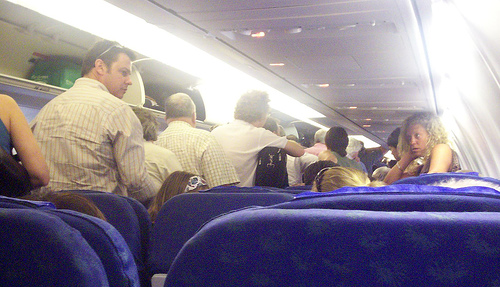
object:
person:
[259, 120, 279, 137]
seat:
[154, 205, 500, 287]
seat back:
[166, 209, 497, 285]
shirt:
[27, 76, 164, 205]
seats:
[146, 184, 297, 278]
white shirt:
[207, 118, 287, 188]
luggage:
[28, 51, 83, 90]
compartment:
[0, 0, 141, 109]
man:
[30, 39, 165, 210]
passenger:
[148, 91, 241, 189]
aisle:
[0, 143, 499, 220]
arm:
[255, 126, 305, 157]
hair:
[397, 108, 445, 171]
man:
[205, 88, 303, 186]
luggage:
[237, 139, 302, 191]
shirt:
[153, 121, 238, 191]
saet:
[0, 205, 112, 286]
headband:
[310, 167, 332, 193]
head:
[310, 165, 373, 193]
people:
[124, 104, 185, 212]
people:
[318, 126, 369, 178]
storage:
[203, 15, 438, 89]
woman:
[380, 109, 461, 185]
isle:
[3, 121, 378, 251]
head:
[395, 111, 449, 157]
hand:
[400, 147, 418, 162]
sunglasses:
[95, 43, 123, 60]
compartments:
[125, 53, 210, 128]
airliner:
[6, 2, 496, 283]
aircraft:
[0, 0, 498, 286]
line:
[0, 35, 395, 197]